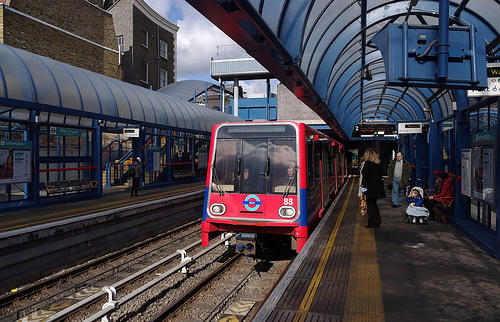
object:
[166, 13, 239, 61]
clouds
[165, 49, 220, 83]
sky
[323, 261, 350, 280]
bricks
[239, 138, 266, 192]
window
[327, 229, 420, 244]
shadows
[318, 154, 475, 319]
sidewalk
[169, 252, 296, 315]
track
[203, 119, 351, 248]
train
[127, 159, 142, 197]
person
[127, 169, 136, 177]
purse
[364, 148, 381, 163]
hair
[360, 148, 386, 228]
lady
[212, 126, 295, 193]
glass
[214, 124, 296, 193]
windshield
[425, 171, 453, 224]
person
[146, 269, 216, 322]
rails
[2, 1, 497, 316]
train station